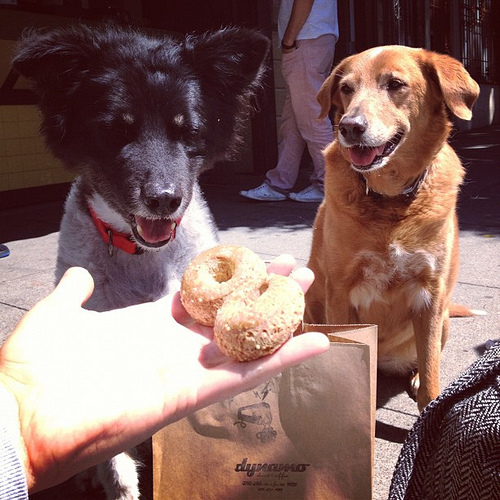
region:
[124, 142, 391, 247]
Two dogs with tongues visible.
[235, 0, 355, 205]
A man is walking behind dogs.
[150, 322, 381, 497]
A brown bag says dynamo.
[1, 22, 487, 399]
Two dogs are looking at a treat.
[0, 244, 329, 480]
A hand is holding food.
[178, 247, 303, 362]
Two tan doughnuts are next to each other.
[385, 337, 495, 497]
The fabric is black and white.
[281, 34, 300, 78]
A hand is in a pocket and has a wristband.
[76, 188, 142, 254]
The collar is red o white fur.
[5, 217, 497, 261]
A shadow line is behind the dogs.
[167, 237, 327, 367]
man holding two donuts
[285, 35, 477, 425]
light colored dog sitting on sidewalk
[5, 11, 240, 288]
dark colored dog sitting on sidewalk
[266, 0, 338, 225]
man walking down the street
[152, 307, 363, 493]
brown bag with dynamo written on it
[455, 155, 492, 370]
sidewalk were people walk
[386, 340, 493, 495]
gray and black hat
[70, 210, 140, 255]
red collar on dog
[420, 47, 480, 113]
dog with his ear down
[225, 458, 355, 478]
dynamo the name of the restaurant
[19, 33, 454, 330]
two dogs and two donuts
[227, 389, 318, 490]
paper bag with a logo for dynamo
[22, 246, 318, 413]
outstretched hand with dog treats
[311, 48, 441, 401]
brown dog with a little white fur on its chest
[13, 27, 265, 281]
black and gray dog with a red collar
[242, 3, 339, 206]
man wearing a white shirt and white shoes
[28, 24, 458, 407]
two dogs sitting on a sidewalk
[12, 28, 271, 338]
black and gray dog looking at donuts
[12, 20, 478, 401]
two dogs outside on a sunny day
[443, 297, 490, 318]
dog's brown tail with a white tip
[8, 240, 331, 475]
Two dog treats in a hand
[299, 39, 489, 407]
A brown furry dog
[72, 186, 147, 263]
Collar around dog's neck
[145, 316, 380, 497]
A brown paper bag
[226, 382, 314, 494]
Writing on the paper bag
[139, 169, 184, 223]
Black nose of a dog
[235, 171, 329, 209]
A pair of white shoes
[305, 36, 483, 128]
A pair of brown dog ears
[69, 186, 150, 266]
Dog collar is red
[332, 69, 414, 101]
A pair of black dog eyes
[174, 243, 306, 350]
two donuts in hand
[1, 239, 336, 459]
hand holding two donuts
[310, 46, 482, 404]
brown dog sitting on ground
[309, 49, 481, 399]
brown dog looking at donuts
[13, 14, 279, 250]
black dog looking at donuts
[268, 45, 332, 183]
man wearing brown pants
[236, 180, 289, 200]
white shoes on man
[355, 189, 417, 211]
red collar on brown dog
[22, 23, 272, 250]
dog looking at donuts